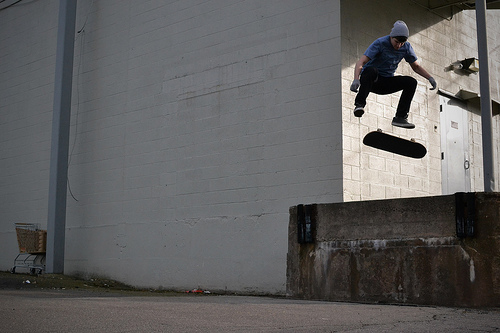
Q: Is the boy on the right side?
A: Yes, the boy is on the right of the image.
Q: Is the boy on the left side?
A: No, the boy is on the right of the image.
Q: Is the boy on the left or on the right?
A: The boy is on the right of the image.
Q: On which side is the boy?
A: The boy is on the right of the image.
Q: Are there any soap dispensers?
A: No, there are no soap dispensers.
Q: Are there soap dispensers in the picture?
A: No, there are no soap dispensers.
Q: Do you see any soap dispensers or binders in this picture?
A: No, there are no soap dispensers or binders.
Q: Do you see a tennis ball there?
A: No, there are no tennis balls.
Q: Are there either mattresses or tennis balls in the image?
A: No, there are no tennis balls or mattresses.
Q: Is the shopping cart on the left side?
A: Yes, the shopping cart is on the left of the image.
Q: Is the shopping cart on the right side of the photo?
A: No, the shopping cart is on the left of the image.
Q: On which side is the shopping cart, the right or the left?
A: The shopping cart is on the left of the image.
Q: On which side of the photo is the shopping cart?
A: The shopping cart is on the left of the image.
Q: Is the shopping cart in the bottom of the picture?
A: Yes, the shopping cart is in the bottom of the image.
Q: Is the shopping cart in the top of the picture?
A: No, the shopping cart is in the bottom of the image.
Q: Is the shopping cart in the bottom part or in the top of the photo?
A: The shopping cart is in the bottom of the image.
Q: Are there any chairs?
A: No, there are no chairs.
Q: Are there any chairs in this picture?
A: No, there are no chairs.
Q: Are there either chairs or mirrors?
A: No, there are no chairs or mirrors.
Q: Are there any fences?
A: No, there are no fences.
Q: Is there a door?
A: Yes, there is a door.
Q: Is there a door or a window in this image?
A: Yes, there is a door.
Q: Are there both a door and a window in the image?
A: No, there is a door but no windows.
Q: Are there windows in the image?
A: No, there are no windows.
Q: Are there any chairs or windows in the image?
A: No, there are no windows or chairs.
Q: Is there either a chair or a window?
A: No, there are no windows or chairs.